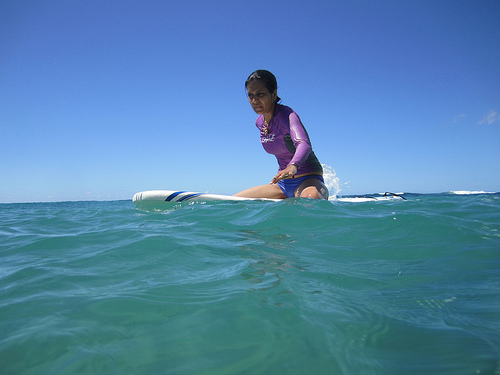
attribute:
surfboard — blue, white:
[131, 189, 401, 202]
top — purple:
[254, 102, 324, 176]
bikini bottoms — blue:
[272, 170, 323, 200]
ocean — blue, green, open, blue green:
[0, 189, 498, 374]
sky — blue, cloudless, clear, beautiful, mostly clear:
[1, 0, 499, 204]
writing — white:
[258, 132, 277, 145]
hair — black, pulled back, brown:
[245, 66, 281, 105]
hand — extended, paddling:
[271, 162, 298, 184]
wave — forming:
[213, 197, 340, 224]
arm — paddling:
[271, 112, 313, 175]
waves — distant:
[351, 188, 499, 198]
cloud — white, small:
[459, 109, 498, 128]